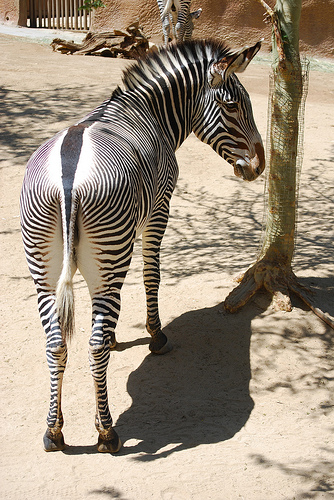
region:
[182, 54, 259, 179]
face of the zebra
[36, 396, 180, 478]
back legs of the zebra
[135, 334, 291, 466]
shadow of the zebra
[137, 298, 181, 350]
front leg of the zebra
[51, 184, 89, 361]
tail of the zebra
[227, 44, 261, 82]
ear of the zebra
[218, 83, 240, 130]
eye of the zebra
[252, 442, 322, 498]
shadow of the trees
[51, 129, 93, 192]
a black line in the zebra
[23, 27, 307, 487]
a zebra standing on ground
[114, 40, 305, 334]
the zebra has stripes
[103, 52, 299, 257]
zebra is looking to its side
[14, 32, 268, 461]
zebra standing on the dirt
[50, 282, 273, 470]
shadow from the zebra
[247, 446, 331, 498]
shadows on the ground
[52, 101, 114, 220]
thick black stripe running along the zebra's back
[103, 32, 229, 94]
hair along the neck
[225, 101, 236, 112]
eye on the side of the head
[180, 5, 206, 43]
head bent down to the ground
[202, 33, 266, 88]
two ears sticking off the top of the head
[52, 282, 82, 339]
hair on the bottom of the tail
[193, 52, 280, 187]
black and white stripes on the face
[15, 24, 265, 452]
black and white zebra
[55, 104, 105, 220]
thick black stripe running down the back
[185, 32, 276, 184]
head is turned to the side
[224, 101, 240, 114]
eye on the side of the face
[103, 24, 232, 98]
hair running down the neck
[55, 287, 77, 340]
hair on the end of the tail